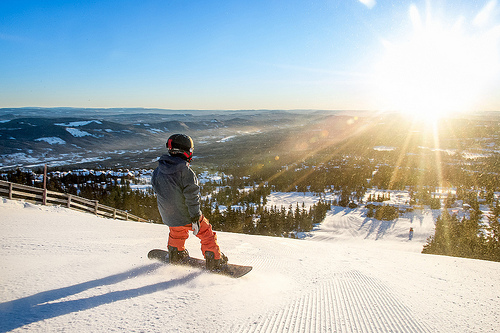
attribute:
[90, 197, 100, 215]
board — wooden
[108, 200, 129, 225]
board — wooden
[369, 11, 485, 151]
sun — bright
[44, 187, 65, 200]
board — wooden